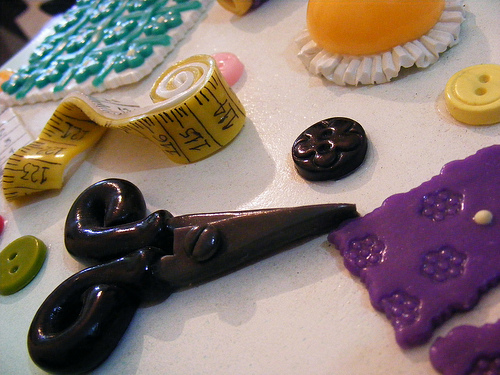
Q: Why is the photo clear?
A: To be seen.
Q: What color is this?
A: Black.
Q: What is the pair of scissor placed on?
A: Table.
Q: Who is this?
A: No one.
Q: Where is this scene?
A: On a craft table.